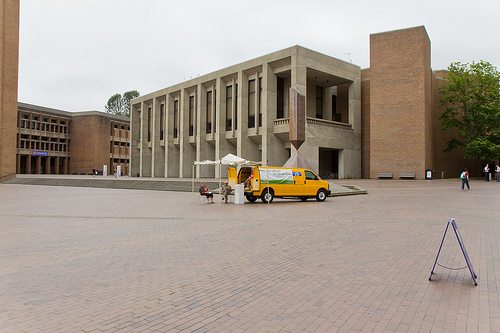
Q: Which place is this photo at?
A: It is at the walkway.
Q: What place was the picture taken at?
A: It was taken at the walkway.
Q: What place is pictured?
A: It is a walkway.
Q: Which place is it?
A: It is a walkway.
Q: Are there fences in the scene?
A: No, there are no fences.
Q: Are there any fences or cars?
A: No, there are no fences or cars.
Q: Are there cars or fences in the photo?
A: No, there are no fences or cars.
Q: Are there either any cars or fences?
A: No, there are no cars or fences.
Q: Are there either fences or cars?
A: No, there are no cars or fences.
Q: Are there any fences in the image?
A: No, there are no fences.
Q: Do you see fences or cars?
A: No, there are no fences or cars.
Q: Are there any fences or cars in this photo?
A: No, there are no fences or cars.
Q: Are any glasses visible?
A: No, there are no glasses.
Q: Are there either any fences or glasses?
A: No, there are no glasses or fences.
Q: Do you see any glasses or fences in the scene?
A: No, there are no glasses or fences.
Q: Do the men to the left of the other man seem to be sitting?
A: Yes, the men are sitting.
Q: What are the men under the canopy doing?
A: The men are sitting.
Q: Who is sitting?
A: The men are sitting.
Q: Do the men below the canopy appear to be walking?
A: No, the men are sitting.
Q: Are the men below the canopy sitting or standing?
A: The men are sitting.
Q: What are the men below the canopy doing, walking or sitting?
A: The men are sitting.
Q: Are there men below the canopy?
A: Yes, there are men below the canopy.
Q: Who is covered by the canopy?
A: The men are covered by the canopy.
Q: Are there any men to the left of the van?
A: Yes, there are men to the left of the van.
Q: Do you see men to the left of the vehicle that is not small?
A: Yes, there are men to the left of the van.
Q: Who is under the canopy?
A: The men are under the canopy.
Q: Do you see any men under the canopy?
A: Yes, there are men under the canopy.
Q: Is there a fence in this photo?
A: No, there are no fences.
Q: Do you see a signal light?
A: No, there are no traffic lights.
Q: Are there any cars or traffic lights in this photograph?
A: No, there are no traffic lights or cars.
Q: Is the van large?
A: Yes, the van is large.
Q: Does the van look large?
A: Yes, the van is large.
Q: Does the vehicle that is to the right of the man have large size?
A: Yes, the van is large.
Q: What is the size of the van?
A: The van is large.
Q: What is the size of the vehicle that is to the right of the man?
A: The van is large.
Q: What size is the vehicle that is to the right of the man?
A: The van is large.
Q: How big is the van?
A: The van is large.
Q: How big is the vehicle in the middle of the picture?
A: The van is large.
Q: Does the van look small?
A: No, the van is large.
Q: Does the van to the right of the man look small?
A: No, the van is large.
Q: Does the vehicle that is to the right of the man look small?
A: No, the van is large.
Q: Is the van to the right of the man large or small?
A: The van is large.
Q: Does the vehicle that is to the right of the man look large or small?
A: The van is large.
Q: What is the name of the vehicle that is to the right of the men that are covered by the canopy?
A: The vehicle is a van.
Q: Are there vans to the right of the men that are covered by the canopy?
A: Yes, there is a van to the right of the men.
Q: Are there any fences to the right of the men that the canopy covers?
A: No, there is a van to the right of the men.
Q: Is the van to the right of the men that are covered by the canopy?
A: Yes, the van is to the right of the men.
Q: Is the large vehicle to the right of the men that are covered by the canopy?
A: Yes, the van is to the right of the men.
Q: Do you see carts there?
A: No, there are no carts.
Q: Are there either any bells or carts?
A: No, there are no carts or bells.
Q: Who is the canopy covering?
A: The canopy is covering the men.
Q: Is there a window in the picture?
A: Yes, there is a window.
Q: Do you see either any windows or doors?
A: Yes, there is a window.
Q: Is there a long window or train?
A: Yes, there is a long window.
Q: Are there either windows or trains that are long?
A: Yes, the window is long.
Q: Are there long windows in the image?
A: Yes, there is a long window.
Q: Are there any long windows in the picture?
A: Yes, there is a long window.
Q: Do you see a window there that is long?
A: Yes, there is a window that is long.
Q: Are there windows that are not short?
A: Yes, there is a long window.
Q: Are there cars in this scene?
A: No, there are no cars.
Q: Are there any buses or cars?
A: No, there are no cars or buses.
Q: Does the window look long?
A: Yes, the window is long.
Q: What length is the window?
A: The window is long.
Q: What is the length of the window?
A: The window is long.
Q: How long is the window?
A: The window is long.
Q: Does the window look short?
A: No, the window is long.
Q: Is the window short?
A: No, the window is long.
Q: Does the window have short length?
A: No, the window is long.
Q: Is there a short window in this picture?
A: No, there is a window but it is long.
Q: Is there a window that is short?
A: No, there is a window but it is long.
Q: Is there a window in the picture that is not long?
A: No, there is a window but it is long.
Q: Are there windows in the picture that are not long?
A: No, there is a window but it is long.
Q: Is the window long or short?
A: The window is long.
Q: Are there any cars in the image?
A: No, there are no cars.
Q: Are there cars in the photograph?
A: No, there are no cars.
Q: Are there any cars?
A: No, there are no cars.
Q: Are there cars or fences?
A: No, there are no cars or fences.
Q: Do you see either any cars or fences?
A: No, there are no cars or fences.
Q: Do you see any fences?
A: No, there are no fences.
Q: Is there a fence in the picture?
A: No, there are no fences.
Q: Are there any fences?
A: No, there are no fences.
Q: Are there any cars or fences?
A: No, there are no fences or cars.